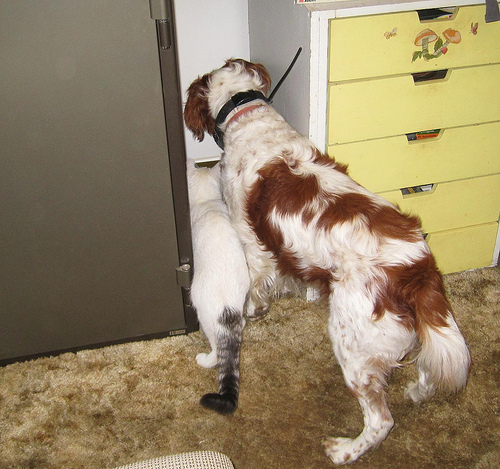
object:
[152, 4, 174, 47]
hinge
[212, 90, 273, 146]
black collar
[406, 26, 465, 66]
mushroom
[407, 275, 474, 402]
tail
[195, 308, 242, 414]
tail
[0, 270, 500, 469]
carpet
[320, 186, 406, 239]
dresses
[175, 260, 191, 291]
hinge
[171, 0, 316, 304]
wall opening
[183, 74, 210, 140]
ear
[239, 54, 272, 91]
ear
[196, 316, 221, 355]
leg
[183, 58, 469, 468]
dog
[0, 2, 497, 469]
room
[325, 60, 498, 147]
drawer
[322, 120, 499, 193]
drawer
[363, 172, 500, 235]
drawer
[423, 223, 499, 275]
drawer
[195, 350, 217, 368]
paw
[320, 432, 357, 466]
paw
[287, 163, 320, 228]
fur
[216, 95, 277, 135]
neck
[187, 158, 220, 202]
head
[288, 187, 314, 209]
spot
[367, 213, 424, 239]
spot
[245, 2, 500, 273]
chest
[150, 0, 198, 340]
bottom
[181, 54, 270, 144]
head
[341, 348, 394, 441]
leg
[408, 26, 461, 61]
decoration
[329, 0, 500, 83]
drawer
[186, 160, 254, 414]
cat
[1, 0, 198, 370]
door